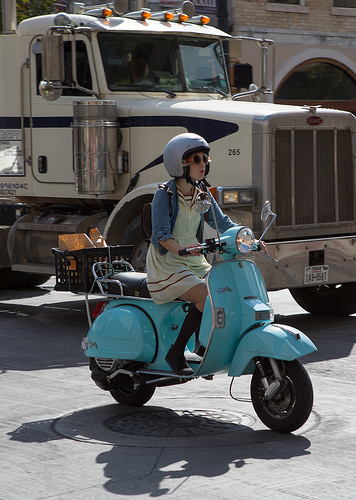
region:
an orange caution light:
[102, 7, 109, 14]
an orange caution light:
[145, 11, 154, 18]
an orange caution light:
[165, 12, 180, 23]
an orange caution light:
[177, 12, 190, 20]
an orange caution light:
[203, 14, 211, 22]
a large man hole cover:
[98, 397, 248, 445]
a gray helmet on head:
[164, 133, 211, 177]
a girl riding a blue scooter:
[31, 137, 332, 430]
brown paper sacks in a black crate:
[60, 227, 106, 255]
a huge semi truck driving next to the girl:
[6, 8, 353, 284]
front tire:
[297, 385, 315, 408]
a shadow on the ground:
[107, 445, 178, 494]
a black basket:
[55, 252, 83, 289]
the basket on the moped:
[55, 250, 91, 288]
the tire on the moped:
[111, 391, 131, 407]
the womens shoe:
[168, 352, 191, 378]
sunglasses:
[190, 154, 210, 164]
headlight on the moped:
[235, 228, 256, 254]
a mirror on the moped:
[256, 201, 277, 218]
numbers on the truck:
[222, 148, 242, 157]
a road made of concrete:
[0, 275, 355, 499]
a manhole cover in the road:
[103, 408, 255, 436]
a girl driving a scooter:
[145, 132, 268, 376]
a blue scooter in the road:
[76, 190, 318, 432]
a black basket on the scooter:
[51, 244, 133, 293]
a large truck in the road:
[0, 0, 355, 315]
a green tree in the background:
[14, 0, 57, 24]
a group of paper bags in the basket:
[58, 227, 107, 283]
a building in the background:
[68, 0, 355, 116]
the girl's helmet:
[163, 132, 211, 187]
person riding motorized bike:
[43, 130, 331, 423]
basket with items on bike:
[53, 223, 134, 292]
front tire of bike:
[235, 354, 321, 423]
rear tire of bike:
[92, 352, 155, 405]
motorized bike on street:
[63, 198, 309, 419]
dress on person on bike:
[149, 183, 214, 303]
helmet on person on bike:
[154, 131, 228, 182]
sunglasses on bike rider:
[175, 151, 210, 165]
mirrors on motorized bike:
[194, 187, 277, 222]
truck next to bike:
[2, 5, 355, 327]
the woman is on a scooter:
[81, 105, 307, 439]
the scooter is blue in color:
[85, 195, 297, 395]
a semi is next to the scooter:
[13, 7, 352, 339]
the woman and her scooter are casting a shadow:
[11, 401, 315, 498]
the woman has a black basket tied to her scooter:
[49, 215, 132, 298]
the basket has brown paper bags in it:
[58, 225, 127, 265]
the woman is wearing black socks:
[171, 299, 202, 355]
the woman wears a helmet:
[156, 126, 213, 181]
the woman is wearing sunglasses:
[185, 152, 210, 165]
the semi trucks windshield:
[100, 36, 228, 88]